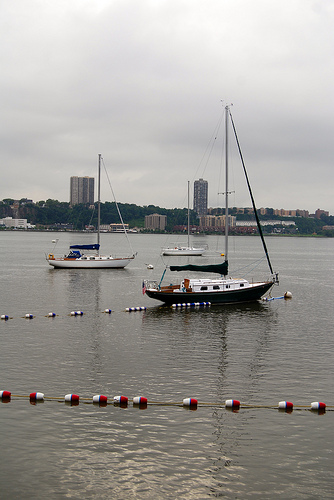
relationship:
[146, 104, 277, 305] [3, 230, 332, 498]
boat in water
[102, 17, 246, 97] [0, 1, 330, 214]
cloud in sky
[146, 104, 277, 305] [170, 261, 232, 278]
boat with sail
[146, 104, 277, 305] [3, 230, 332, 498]
boat anchored in water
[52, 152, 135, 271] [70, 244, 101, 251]
boat with sail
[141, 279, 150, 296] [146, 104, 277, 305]
flag on boat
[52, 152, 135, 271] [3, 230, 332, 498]
boat in water